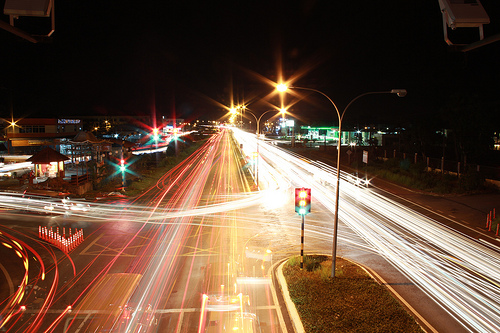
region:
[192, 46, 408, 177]
Lights on the road.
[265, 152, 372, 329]
Sign on the ground.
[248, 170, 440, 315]
Grass in the median.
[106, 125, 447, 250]
Lanes in the road.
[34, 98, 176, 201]
Buildings in the background.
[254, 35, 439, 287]
Light pole on the ground.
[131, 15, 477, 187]
Dark sky in the background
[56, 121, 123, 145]
Words on the building.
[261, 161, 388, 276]
Red and green sign.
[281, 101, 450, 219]
Gas station in the background.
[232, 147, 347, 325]
a street light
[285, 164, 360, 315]
a street light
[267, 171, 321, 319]
a street light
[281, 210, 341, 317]
a street light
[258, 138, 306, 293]
a street light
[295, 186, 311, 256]
electronic stop light on pole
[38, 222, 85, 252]
orand and white street cones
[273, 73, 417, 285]
grey metal street lamp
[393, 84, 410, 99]
burned out street light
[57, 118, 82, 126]
lighted store name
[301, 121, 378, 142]
gas station by road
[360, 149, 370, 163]
white and black street sign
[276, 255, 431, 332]
green grass road barrier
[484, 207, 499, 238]
street cones in grass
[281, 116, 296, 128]
lighted store sign on pole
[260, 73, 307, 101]
glowing light on pole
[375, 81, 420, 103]
light on horizontal pole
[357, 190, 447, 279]
blurred lights of traffic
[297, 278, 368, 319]
grass on highway median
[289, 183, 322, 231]
tarffic light on pole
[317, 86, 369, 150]
two curved poles on straight pole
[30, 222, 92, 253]
orange and white cones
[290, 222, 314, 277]
black and yellow pole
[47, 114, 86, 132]
sign on side of building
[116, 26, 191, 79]
black of night sky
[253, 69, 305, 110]
flash of light on street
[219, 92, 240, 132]
flash of light on street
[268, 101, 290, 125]
flash of light on street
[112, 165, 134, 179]
flash of light on street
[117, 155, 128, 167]
flash of light on street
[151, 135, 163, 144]
flash of light on street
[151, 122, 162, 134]
flash of light on street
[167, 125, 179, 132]
flash of light on street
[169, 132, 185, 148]
flash of light on street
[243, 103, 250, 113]
flash of light on street